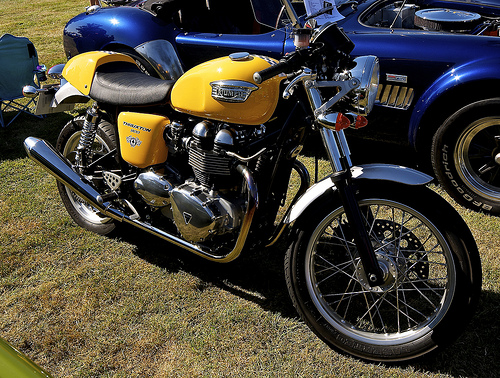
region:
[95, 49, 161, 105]
black seat on motorcycle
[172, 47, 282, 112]
yellow tank on bike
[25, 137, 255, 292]
exhaust pip on the motorcycle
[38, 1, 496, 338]
motorcycle is next to car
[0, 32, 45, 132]
foldable chair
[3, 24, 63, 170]
chair is behind the motorcycle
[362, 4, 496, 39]
engine of car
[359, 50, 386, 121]
headlight of the motorcycle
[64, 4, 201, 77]
blue on the car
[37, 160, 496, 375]
motorcycle parked in car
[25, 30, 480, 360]
yellow and black motorcycle parked on grass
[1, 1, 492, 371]
dried brown grass with green grass mixed in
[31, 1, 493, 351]
blue sportscar behind motorcycle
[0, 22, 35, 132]
folding chair with stretched fabric behind vehicles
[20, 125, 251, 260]
angled silver pipe ending in elongated cone shape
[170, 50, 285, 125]
raised metal panel on curved yellow cover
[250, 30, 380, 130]
black handlebars over large headlight and turn signals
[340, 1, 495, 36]
blue lid on flat and round wheel under open hood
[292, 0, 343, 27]
black and white papers under windshield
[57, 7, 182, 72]
curved blue and silver wheel covering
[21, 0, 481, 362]
The motorcycle is yellow.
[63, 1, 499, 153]
The car is blue.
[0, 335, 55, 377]
A green painted surface in the sun.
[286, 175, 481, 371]
The tire is black.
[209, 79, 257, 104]
The chrome nameplate says Triumph.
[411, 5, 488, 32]
The air cleaer is chrome.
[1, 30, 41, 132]
A folding chair is on the ground.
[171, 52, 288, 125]
A motorcycle gas tnk with gas cap.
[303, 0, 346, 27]
A paper is under a windshield wiper.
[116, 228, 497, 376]
A mototcycle shadow on the ground.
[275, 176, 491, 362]
tire on a motorcycle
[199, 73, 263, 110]
logo on a motorcycle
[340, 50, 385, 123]
headlight on a motorcycle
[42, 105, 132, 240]
tire on a motorcycle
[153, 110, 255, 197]
engine on a motorcycle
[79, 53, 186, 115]
black leather motorcycle seat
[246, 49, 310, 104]
black handlebar on motorcycle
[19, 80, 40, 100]
tail light on motorcycle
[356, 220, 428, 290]
disc brake on motorcycle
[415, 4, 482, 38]
air filter on car engine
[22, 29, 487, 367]
motorcycle parked on the grass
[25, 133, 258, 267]
shiny long chrome exhaust pipe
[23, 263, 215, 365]
dried brown grass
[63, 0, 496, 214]
shiny blue vintage car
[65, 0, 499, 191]
blue car behind a motorcycle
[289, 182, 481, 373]
black tire on a motorcycle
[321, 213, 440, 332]
shiny chrome spokes on the wheel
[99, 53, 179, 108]
black seat of a motorcycle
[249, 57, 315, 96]
handlebar of a motorcycle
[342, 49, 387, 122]
headlamp on a motorcycle